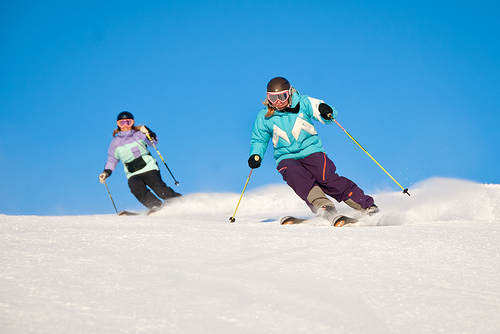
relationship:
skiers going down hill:
[66, 59, 429, 260] [24, 202, 452, 314]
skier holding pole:
[88, 93, 223, 229] [133, 114, 192, 190]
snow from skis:
[32, 221, 213, 305] [137, 188, 239, 225]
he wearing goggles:
[227, 47, 381, 240] [263, 85, 301, 106]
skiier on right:
[227, 47, 381, 240] [236, 37, 466, 261]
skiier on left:
[50, 86, 186, 241] [9, 57, 207, 278]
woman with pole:
[50, 86, 186, 241] [133, 114, 192, 190]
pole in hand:
[133, 114, 192, 190] [142, 111, 170, 153]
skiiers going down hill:
[66, 59, 429, 260] [1, 74, 456, 331]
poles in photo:
[133, 114, 192, 190] [1, 74, 456, 331]